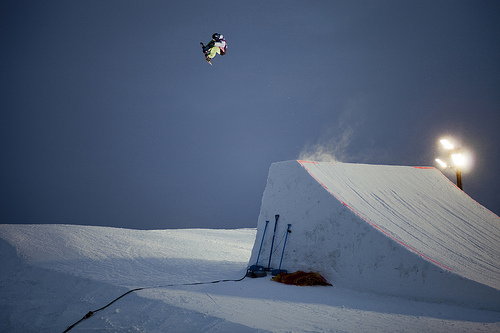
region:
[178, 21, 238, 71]
Man jumping in the air on a snow board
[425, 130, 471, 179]
Lights attached to a pole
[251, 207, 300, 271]
ski poles on the side of a ramp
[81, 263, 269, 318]
electric wire on the ground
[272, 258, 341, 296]
cloth on the ground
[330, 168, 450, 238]
snow on top of at ramp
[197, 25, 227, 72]
Man jumping in the air on a snow board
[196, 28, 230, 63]
a snowboarder high in the air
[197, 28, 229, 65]
a snowboarder who rode off a huge ramp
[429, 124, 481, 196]
bright lights illuminating the ramp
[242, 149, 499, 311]
a huge snowboard ramp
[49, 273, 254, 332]
black cord leading down the mountain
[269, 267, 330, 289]
an orange fabric next to the ramp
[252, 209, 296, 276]
three poles lying on side of ramp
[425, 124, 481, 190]
lights are very bright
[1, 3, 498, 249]
sky is completely clear and blue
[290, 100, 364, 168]
snow dust flying off ramp from snowboarder jumping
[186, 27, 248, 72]
A person in the air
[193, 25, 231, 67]
A snowboarder in the air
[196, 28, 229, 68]
A snowboarder doing a trick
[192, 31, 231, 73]
A snowboarder doing a trick in the air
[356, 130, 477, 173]
Lights providing light in the night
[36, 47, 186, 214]
Large body of night skies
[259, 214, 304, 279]
Equipment by the snow ramp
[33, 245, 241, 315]
Shadow from the snow ramp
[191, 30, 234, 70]
The person is in midair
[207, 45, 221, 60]
The person has a green pant leg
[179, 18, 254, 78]
This person is snowboarding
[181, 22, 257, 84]
The person is in the air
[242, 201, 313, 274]
Skis leaning against the hill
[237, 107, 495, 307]
A ramp made of snow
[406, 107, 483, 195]
Three lights turned on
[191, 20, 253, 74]
The person is wearing a helmet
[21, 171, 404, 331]
Snow is covering the ground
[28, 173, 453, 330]
Picture taken on a mountain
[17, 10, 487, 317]
Picture taken in the evening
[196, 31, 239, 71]
Right hand is on the snowboard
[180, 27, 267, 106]
a snowboarder in the air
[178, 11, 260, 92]
a snowboarder making a jump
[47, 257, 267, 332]
a long black strap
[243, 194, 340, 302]
three poles against ramp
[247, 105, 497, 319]
a ramp for doing tricks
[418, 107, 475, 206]
three lights are on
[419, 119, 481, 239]
three lights on a pole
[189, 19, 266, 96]
a person in the air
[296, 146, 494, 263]
red line around ramp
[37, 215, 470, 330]
shadow from the ramp